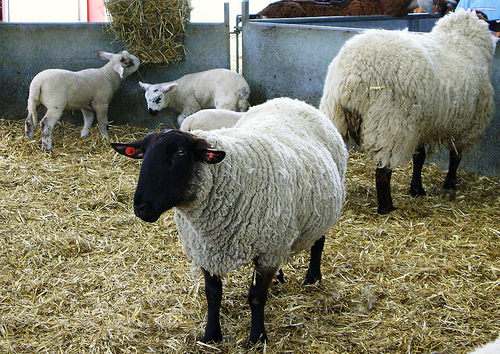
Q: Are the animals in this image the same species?
A: Yes, all the animals are sheep.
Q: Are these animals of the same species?
A: Yes, all the animals are sheep.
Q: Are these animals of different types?
A: No, all the animals are sheep.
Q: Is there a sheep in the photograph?
A: Yes, there is a sheep.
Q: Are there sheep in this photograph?
A: Yes, there is a sheep.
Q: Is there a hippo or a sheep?
A: Yes, there is a sheep.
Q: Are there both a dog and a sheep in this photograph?
A: No, there is a sheep but no dogs.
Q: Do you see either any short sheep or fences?
A: Yes, there is a short sheep.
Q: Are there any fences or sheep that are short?
A: Yes, the sheep is short.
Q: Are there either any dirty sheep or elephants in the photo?
A: Yes, there is a dirty sheep.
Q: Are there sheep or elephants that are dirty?
A: Yes, the sheep is dirty.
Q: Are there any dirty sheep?
A: Yes, there is a dirty sheep.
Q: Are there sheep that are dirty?
A: Yes, there is a sheep that is dirty.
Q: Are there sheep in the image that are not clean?
A: Yes, there is a dirty sheep.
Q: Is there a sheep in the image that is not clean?
A: Yes, there is a dirty sheep.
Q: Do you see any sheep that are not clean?
A: Yes, there is a dirty sheep.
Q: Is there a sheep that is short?
A: Yes, there is a short sheep.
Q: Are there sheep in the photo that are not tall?
A: Yes, there is a short sheep.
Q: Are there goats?
A: No, there are no goats.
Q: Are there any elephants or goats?
A: No, there are no goats or elephants.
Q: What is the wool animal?
A: The animal is a sheep.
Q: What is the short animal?
A: The animal is a sheep.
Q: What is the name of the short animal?
A: The animal is a sheep.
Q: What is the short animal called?
A: The animal is a sheep.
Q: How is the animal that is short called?
A: The animal is a sheep.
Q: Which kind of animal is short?
A: The animal is a sheep.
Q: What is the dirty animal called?
A: The animal is a sheep.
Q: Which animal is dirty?
A: The animal is a sheep.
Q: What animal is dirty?
A: The animal is a sheep.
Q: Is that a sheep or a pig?
A: That is a sheep.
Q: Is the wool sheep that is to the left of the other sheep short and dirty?
A: Yes, the sheep is short and dirty.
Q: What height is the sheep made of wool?
A: The sheep is short.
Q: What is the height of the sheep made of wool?
A: The sheep is short.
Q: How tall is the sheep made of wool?
A: The sheep is short.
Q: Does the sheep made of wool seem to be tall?
A: No, the sheep is short.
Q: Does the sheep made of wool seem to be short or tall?
A: The sheep is short.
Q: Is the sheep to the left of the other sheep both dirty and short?
A: Yes, the sheep is dirty and short.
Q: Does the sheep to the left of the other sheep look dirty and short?
A: Yes, the sheep is dirty and short.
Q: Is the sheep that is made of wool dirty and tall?
A: No, the sheep is dirty but short.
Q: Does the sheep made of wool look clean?
A: No, the sheep is dirty.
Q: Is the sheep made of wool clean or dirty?
A: The sheep is dirty.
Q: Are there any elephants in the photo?
A: No, there are no elephants.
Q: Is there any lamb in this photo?
A: Yes, there is a lamb.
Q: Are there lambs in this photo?
A: Yes, there is a lamb.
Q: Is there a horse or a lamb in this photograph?
A: Yes, there is a lamb.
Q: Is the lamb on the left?
A: Yes, the lamb is on the left of the image.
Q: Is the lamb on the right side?
A: No, the lamb is on the left of the image.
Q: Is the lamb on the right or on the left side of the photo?
A: The lamb is on the left of the image.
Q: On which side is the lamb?
A: The lamb is on the left of the image.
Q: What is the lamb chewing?
A: The lamb is chewing the hay.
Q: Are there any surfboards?
A: No, there are no surfboards.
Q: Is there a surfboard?
A: No, there are no surfboards.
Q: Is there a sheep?
A: Yes, there is a sheep.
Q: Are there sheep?
A: Yes, there is a sheep.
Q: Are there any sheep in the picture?
A: Yes, there is a sheep.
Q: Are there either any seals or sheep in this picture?
A: Yes, there is a sheep.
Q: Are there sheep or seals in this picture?
A: Yes, there is a sheep.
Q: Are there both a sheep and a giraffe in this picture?
A: No, there is a sheep but no giraffes.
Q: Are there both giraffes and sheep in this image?
A: No, there is a sheep but no giraffes.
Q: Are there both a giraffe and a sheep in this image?
A: No, there is a sheep but no giraffes.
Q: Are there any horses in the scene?
A: No, there are no horses.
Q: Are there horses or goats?
A: No, there are no horses or goats.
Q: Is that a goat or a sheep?
A: That is a sheep.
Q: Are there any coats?
A: Yes, there is a coat.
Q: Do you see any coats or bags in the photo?
A: Yes, there is a coat.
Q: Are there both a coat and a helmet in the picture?
A: No, there is a coat but no helmets.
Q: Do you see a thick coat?
A: Yes, there is a thick coat.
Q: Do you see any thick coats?
A: Yes, there is a thick coat.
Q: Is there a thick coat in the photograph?
A: Yes, there is a thick coat.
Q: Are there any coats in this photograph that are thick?
A: Yes, there is a coat that is thick.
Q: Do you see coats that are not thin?
A: Yes, there is a thick coat.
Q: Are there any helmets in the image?
A: No, there are no helmets.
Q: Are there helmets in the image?
A: No, there are no helmets.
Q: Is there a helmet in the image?
A: No, there are no helmets.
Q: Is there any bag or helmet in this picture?
A: No, there are no helmets or bags.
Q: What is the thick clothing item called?
A: The clothing item is a coat.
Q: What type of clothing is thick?
A: The clothing is a coat.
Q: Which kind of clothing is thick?
A: The clothing is a coat.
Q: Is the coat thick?
A: Yes, the coat is thick.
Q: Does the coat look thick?
A: Yes, the coat is thick.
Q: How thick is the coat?
A: The coat is thick.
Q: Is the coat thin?
A: No, the coat is thick.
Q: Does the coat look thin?
A: No, the coat is thick.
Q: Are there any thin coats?
A: No, there is a coat but it is thick.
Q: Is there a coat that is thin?
A: No, there is a coat but it is thick.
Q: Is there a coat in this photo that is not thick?
A: No, there is a coat but it is thick.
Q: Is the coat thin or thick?
A: The coat is thick.